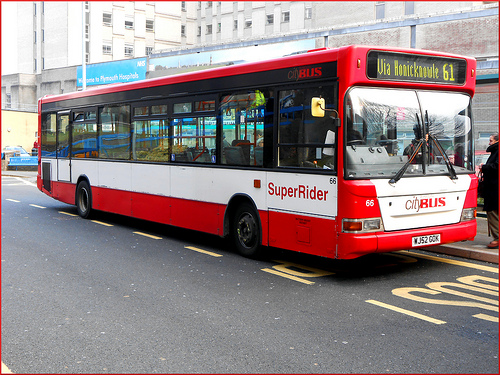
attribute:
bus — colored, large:
[37, 45, 477, 260]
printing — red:
[269, 182, 328, 203]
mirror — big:
[311, 97, 341, 128]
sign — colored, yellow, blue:
[77, 59, 149, 89]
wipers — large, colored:
[389, 111, 458, 184]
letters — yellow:
[271, 252, 499, 337]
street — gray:
[0, 171, 499, 373]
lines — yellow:
[0, 175, 498, 327]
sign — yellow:
[365, 48, 467, 86]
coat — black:
[481, 142, 500, 211]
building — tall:
[16, 1, 500, 74]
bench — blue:
[8, 157, 39, 168]